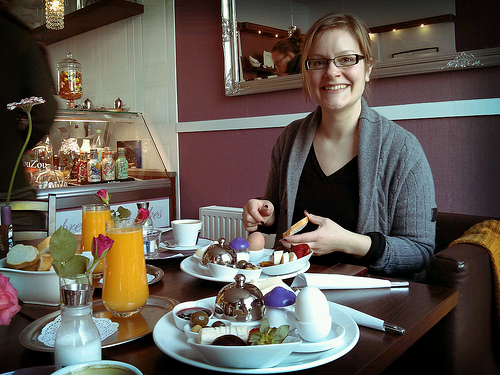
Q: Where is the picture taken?
A: Restaurant.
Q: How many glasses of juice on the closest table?
A: 2.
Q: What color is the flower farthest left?
A: Pink.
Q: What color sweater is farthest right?
A: Grey.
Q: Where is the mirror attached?
A: To the wall.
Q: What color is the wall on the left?
A: White.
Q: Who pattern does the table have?
A: Woodgrain.